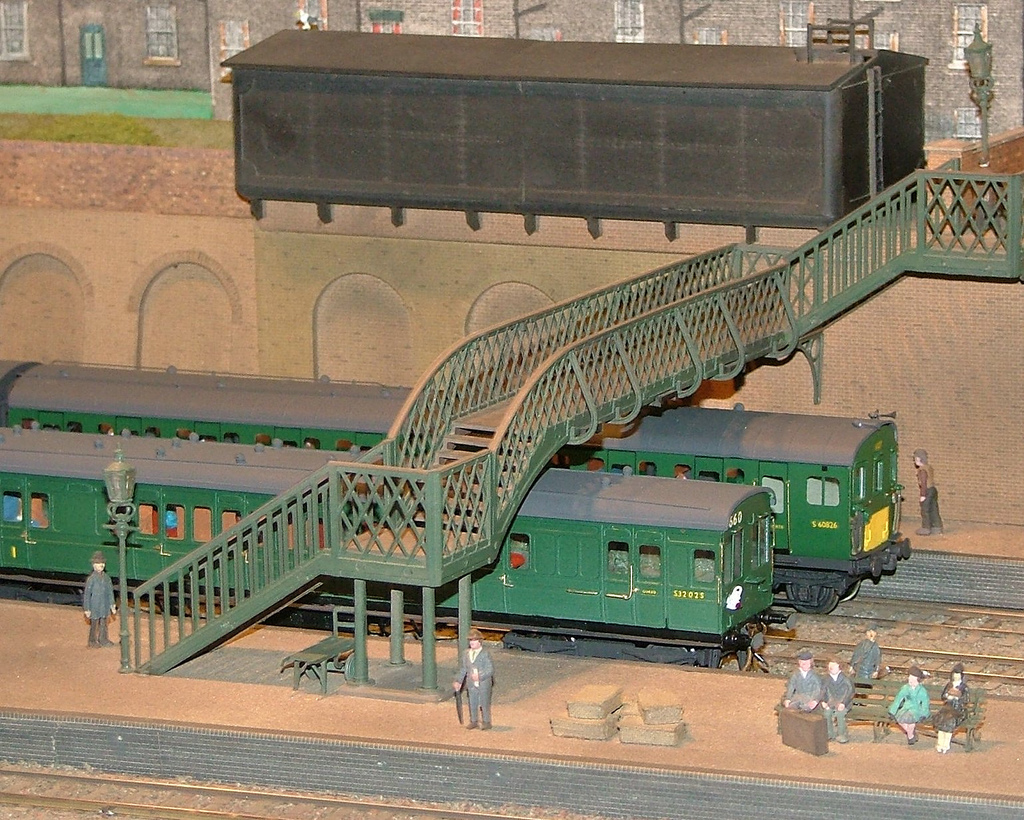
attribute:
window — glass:
[449, 0, 485, 38]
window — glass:
[141, 0, 181, 58]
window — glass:
[215, 15, 253, 80]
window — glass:
[781, 0, 816, 48]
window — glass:
[948, 6, 991, 76]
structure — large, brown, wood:
[220, 24, 932, 244]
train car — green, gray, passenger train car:
[6, 359, 898, 555]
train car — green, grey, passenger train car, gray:
[0, 423, 779, 638]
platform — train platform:
[44, 655, 133, 700]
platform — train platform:
[500, 660, 551, 736]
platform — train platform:
[718, 717, 763, 769]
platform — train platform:
[828, 737, 886, 780]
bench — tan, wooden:
[278, 623, 370, 694]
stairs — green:
[411, 303, 523, 512]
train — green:
[4, 408, 791, 683]